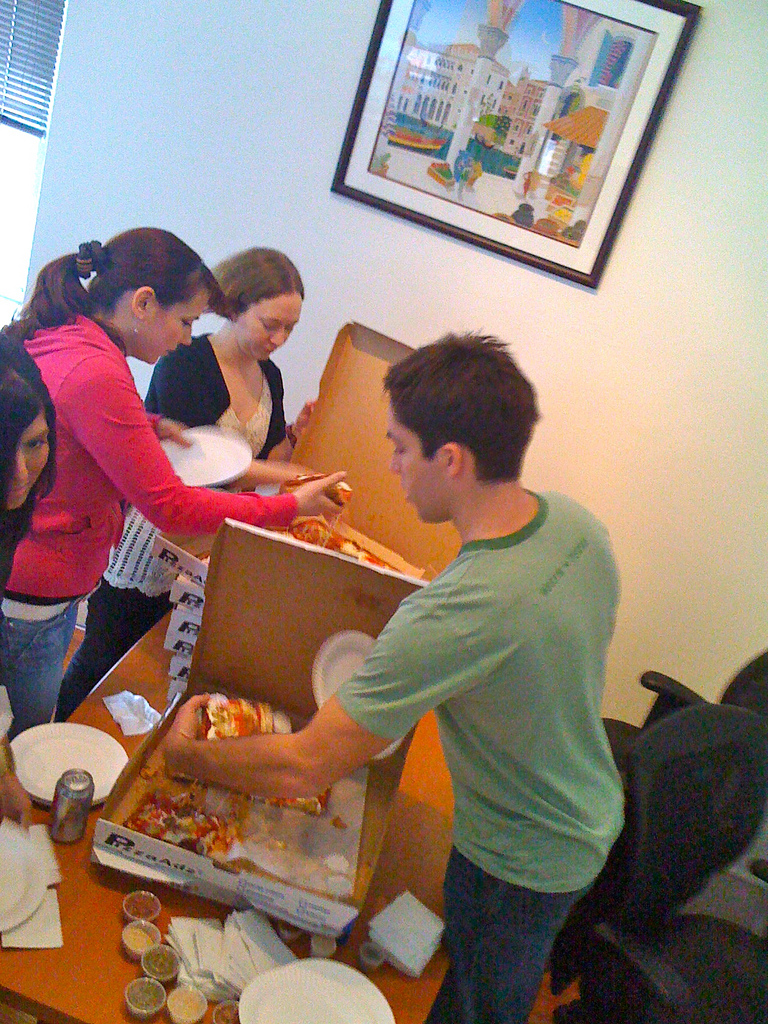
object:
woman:
[0, 331, 60, 674]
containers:
[122, 890, 240, 1022]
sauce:
[122, 918, 161, 957]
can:
[51, 767, 95, 839]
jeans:
[0, 600, 79, 743]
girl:
[0, 227, 352, 744]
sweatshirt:
[5, 314, 298, 601]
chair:
[551, 671, 768, 996]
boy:
[165, 332, 625, 1022]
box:
[89, 517, 430, 938]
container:
[123, 890, 161, 922]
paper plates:
[237, 956, 397, 1022]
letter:
[540, 575, 557, 595]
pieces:
[175, 791, 251, 856]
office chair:
[552, 915, 768, 1024]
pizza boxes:
[151, 532, 210, 702]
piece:
[200, 692, 235, 739]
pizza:
[279, 473, 402, 574]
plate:
[160, 425, 252, 486]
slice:
[149, 792, 197, 844]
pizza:
[124, 692, 332, 862]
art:
[331, 0, 702, 288]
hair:
[0, 339, 58, 585]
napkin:
[163, 911, 297, 1002]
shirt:
[336, 488, 625, 891]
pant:
[443, 844, 595, 1020]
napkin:
[367, 889, 446, 979]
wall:
[19, 0, 767, 728]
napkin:
[102, 690, 162, 737]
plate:
[9, 722, 128, 809]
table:
[0, 600, 453, 1024]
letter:
[551, 573, 557, 581]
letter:
[557, 569, 565, 578]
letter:
[575, 547, 583, 560]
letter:
[564, 559, 572, 567]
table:
[6, 610, 461, 1021]